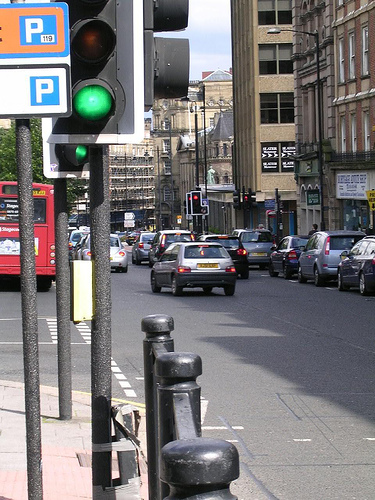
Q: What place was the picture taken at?
A: It was taken at the street.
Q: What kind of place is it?
A: It is a street.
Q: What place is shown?
A: It is a street.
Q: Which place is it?
A: It is a street.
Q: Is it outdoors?
A: Yes, it is outdoors.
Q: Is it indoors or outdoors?
A: It is outdoors.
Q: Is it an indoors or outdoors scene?
A: It is outdoors.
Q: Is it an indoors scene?
A: No, it is outdoors.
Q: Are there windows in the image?
A: Yes, there is a window.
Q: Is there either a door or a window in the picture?
A: Yes, there is a window.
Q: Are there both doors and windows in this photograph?
A: No, there is a window but no doors.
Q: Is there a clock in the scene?
A: No, there are no clocks.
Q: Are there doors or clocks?
A: No, there are no clocks or doors.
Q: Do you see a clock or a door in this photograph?
A: No, there are no clocks or doors.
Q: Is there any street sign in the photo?
A: Yes, there is a street sign.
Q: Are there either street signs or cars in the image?
A: Yes, there is a street sign.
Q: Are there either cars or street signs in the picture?
A: Yes, there is a street sign.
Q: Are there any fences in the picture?
A: No, there are no fences.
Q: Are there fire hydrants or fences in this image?
A: No, there are no fences or fire hydrants.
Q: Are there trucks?
A: No, there are no trucks.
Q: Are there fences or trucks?
A: No, there are no trucks or fences.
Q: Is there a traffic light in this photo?
A: Yes, there is a traffic light.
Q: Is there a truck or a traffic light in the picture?
A: Yes, there is a traffic light.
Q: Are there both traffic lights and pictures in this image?
A: No, there is a traffic light but no pictures.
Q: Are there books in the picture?
A: No, there are no books.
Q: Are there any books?
A: No, there are no books.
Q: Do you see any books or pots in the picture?
A: No, there are no books or pots.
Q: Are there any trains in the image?
A: No, there are no trains.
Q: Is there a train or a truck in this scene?
A: No, there are no trains or trucks.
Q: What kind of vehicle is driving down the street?
A: The vehicle is a car.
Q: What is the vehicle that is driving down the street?
A: The vehicle is a car.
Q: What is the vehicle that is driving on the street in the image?
A: The vehicle is a car.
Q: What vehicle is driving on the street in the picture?
A: The vehicle is a car.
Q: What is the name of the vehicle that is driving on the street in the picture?
A: The vehicle is a car.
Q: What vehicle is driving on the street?
A: The vehicle is a car.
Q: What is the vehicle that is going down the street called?
A: The vehicle is a car.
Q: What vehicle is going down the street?
A: The vehicle is a car.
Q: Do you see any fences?
A: No, there are no fences.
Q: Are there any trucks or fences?
A: No, there are no fences or trucks.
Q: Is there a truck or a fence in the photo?
A: No, there are no fences or trucks.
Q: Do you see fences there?
A: No, there are no fences.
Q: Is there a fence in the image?
A: No, there are no fences.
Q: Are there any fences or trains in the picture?
A: No, there are no fences or trains.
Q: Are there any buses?
A: Yes, there is a bus.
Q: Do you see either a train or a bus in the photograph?
A: Yes, there is a bus.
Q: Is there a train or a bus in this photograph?
A: Yes, there is a bus.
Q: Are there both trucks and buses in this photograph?
A: No, there is a bus but no trucks.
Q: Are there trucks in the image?
A: No, there are no trucks.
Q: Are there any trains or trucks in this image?
A: No, there are no trucks or trains.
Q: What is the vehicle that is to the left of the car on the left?
A: The vehicle is a bus.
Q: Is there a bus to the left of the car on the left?
A: Yes, there is a bus to the left of the car.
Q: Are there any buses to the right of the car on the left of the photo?
A: No, the bus is to the left of the car.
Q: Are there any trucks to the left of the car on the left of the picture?
A: No, there is a bus to the left of the car.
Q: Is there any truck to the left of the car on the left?
A: No, there is a bus to the left of the car.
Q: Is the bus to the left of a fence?
A: No, the bus is to the left of the car.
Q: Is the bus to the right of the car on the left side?
A: No, the bus is to the left of the car.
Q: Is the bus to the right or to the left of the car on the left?
A: The bus is to the left of the car.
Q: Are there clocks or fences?
A: No, there are no fences or clocks.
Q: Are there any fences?
A: No, there are no fences.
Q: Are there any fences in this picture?
A: No, there are no fences.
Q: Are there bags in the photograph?
A: No, there are no bags.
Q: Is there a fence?
A: No, there are no fences.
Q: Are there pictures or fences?
A: No, there are no fences or pictures.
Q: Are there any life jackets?
A: No, there are no life jackets.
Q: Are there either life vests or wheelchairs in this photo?
A: No, there are no life vests or wheelchairs.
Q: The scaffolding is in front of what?
A: The scaffolding is in front of the building.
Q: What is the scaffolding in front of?
A: The scaffolding is in front of the building.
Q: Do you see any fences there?
A: No, there are no fences.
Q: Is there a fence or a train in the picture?
A: No, there are no fences or trains.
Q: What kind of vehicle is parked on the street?
A: The vehicle is a car.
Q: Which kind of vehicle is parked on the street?
A: The vehicle is a car.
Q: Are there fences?
A: No, there are no fences.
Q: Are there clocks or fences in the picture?
A: No, there are no fences or clocks.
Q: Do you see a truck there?
A: No, there are no trucks.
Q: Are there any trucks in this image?
A: No, there are no trucks.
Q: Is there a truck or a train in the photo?
A: No, there are no trucks or trains.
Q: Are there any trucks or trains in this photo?
A: No, there are no trucks or trains.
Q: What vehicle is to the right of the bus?
A: The vehicle is a car.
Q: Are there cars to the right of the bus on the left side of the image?
A: Yes, there is a car to the right of the bus.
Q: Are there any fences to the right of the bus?
A: No, there is a car to the right of the bus.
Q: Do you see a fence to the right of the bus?
A: No, there is a car to the right of the bus.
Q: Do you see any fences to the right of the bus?
A: No, there is a car to the right of the bus.